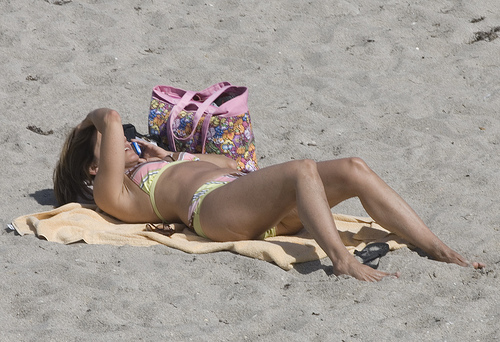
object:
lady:
[47, 106, 486, 286]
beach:
[0, 2, 497, 341]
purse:
[149, 82, 253, 144]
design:
[158, 107, 242, 150]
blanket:
[6, 202, 411, 272]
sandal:
[351, 241, 391, 263]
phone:
[124, 123, 142, 157]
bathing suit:
[129, 150, 201, 219]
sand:
[0, 263, 267, 339]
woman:
[53, 105, 489, 281]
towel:
[8, 201, 301, 271]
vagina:
[268, 228, 283, 231]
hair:
[47, 126, 99, 207]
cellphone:
[124, 144, 147, 157]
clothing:
[125, 148, 204, 217]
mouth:
[123, 146, 132, 156]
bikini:
[126, 148, 239, 238]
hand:
[71, 107, 108, 143]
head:
[68, 108, 140, 180]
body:
[122, 153, 275, 239]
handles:
[166, 81, 227, 153]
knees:
[334, 148, 371, 177]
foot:
[332, 248, 395, 285]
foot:
[425, 238, 488, 279]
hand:
[130, 133, 174, 158]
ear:
[87, 165, 96, 174]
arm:
[75, 107, 144, 194]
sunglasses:
[141, 213, 185, 237]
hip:
[192, 195, 240, 242]